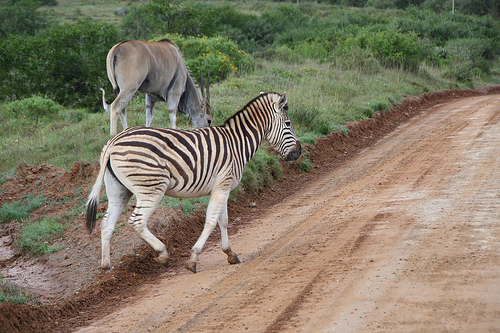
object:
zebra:
[84, 90, 303, 275]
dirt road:
[0, 86, 500, 333]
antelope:
[98, 37, 214, 139]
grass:
[0, 0, 500, 305]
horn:
[205, 70, 211, 116]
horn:
[200, 67, 206, 105]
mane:
[216, 90, 284, 128]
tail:
[83, 146, 112, 235]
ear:
[276, 91, 288, 112]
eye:
[284, 121, 291, 127]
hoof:
[225, 252, 242, 264]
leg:
[184, 178, 235, 274]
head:
[257, 90, 303, 161]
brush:
[0, 118, 81, 302]